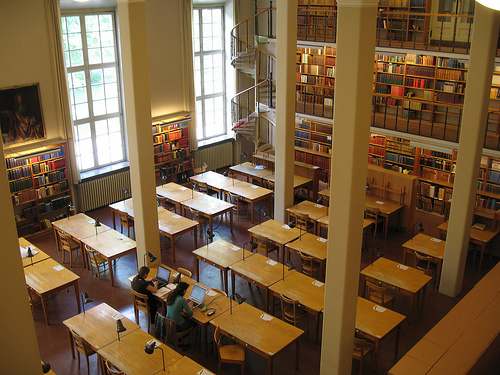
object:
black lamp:
[93, 217, 101, 235]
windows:
[54, 10, 127, 173]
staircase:
[229, 0, 274, 159]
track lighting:
[151, 105, 187, 125]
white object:
[260, 314, 274, 322]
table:
[190, 238, 407, 340]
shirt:
[166, 295, 194, 325]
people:
[166, 281, 197, 343]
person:
[133, 266, 162, 309]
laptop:
[148, 265, 171, 289]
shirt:
[132, 277, 154, 302]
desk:
[189, 170, 272, 202]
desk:
[229, 161, 311, 187]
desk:
[51, 212, 137, 287]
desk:
[156, 206, 201, 262]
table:
[127, 263, 238, 358]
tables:
[315, 176, 415, 236]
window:
[192, 3, 225, 138]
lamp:
[116, 319, 127, 341]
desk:
[62, 302, 212, 375]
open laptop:
[183, 284, 208, 312]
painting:
[0, 82, 49, 149]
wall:
[2, 2, 61, 85]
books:
[5, 145, 73, 235]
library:
[3, 0, 498, 373]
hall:
[3, 0, 500, 375]